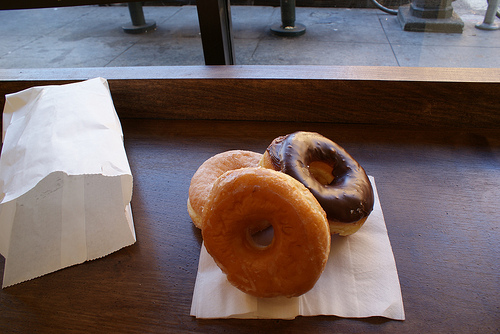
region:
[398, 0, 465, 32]
the base of a pillar on the sidewalk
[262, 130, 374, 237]
a chocolate covered donut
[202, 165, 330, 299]
a glazed donut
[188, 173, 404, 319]
a napkin under donuts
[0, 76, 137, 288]
a white paper bag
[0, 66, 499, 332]
a brown wood counter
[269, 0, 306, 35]
the base of a post on the sidewalk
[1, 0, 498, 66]
a window next to a counter top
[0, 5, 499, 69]
a concrete sidewalk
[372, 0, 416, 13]
the wheel of a bicycle next to a pillar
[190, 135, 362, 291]
Donuts on the napkin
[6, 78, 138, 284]
A white bag on the table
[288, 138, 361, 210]
The donut has chocolate frosting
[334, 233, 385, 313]
A napkin on the table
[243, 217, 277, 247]
The hole of the donut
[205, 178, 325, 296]
The donut is glazed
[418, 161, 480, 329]
A brown table below the donuts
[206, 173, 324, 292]
A donut near the bag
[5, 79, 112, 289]
The bag is empty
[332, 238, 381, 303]
The napkin has food on it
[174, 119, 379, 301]
a group of dough nuts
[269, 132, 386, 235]
a chocolate iced dough nut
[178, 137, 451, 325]
a napkin under the dough nuts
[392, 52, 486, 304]
a brown wooden table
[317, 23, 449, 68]
a concrete side walk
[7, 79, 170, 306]
a white paper bag on a table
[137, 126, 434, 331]
a group of dough nuts on a table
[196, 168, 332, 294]
a glazed dough nut on a napkin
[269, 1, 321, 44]
a metal post on concrete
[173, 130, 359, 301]
Three donuts on a napkin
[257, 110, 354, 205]
Chocolate frosted donut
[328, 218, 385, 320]
White napkin under donuts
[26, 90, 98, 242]
paper bag on a table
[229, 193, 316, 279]
glazed doughnut on a napkin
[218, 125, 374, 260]
Three donuts on a table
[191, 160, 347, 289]
donuts next to eachother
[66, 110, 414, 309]
Donuts and bag together on a table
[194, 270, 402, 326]
napkin opened under donuts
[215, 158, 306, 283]
doughnut standing up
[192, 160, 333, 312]
donut on a napkin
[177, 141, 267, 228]
donut on a napkin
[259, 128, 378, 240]
donut on a napkin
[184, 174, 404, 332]
white napkin on a table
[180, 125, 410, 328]
three donuts on a napkin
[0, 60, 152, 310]
an empty white bag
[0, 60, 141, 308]
white paper bag on table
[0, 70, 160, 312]
empty white bag on table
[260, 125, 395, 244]
donut with chocolate frosting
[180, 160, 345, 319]
donut with no frosting